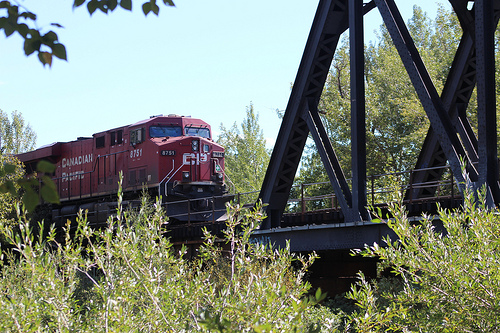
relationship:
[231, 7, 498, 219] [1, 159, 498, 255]
crossbeams support bridge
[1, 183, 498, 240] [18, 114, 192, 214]
railing on side of train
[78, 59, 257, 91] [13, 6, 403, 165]
clouds in sky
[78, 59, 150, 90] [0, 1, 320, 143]
clouds in sky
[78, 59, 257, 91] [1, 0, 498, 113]
clouds in sky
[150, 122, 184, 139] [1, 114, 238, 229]
window on red train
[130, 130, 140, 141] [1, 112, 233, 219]
window on red train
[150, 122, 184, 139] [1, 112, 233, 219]
window on red train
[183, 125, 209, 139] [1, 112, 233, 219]
window on red train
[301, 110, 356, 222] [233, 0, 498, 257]
steel beam supporting bridge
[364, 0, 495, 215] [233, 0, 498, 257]
steel beam supporting bridge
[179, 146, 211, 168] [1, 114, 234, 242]
cp on train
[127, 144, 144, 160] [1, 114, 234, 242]
numbers on train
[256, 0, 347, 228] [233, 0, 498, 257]
beam on bridge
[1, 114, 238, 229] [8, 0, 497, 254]
red train crossing a border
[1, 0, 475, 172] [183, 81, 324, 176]
sky has clouds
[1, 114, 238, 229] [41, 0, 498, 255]
red train on bridge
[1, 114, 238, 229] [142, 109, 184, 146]
red train has window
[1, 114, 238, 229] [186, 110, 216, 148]
red train has window